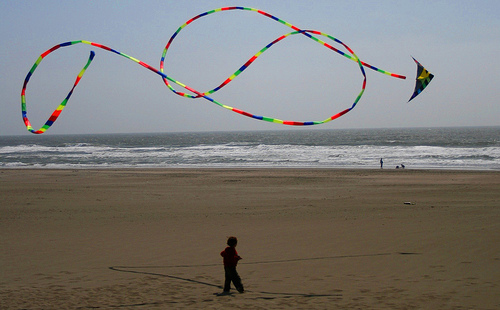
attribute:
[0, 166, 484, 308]
beach — sandy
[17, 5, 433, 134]
kite — shaped, colored, long, flying, colorful, stripped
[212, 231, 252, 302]
boy — small\, little, walking, small, playing, standing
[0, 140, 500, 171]
waves — white, moving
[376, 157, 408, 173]
people — sitting, standing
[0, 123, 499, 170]
ocean — gray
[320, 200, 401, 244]
sand — smooth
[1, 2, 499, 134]
sky — blue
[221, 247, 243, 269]
shirt — red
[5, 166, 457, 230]
beach — sandy